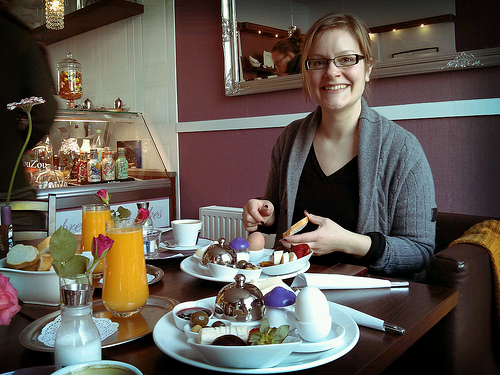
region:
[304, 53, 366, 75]
smiling woman wearing glasses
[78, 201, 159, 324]
two tall glasses of orange juice on table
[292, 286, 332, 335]
white boiled egg in shell in container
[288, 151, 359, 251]
woman wearing black v neck top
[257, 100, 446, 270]
woman wearing grey sweater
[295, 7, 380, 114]
A woman has a smile on her face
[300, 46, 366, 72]
A pair of black glasses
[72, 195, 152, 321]
Two glasses of orange juice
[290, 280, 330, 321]
A white hard boiled egg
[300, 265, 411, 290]
Utensils in a white napkin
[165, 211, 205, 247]
A white coffee cup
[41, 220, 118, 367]
Pink flower in a vase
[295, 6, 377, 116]
Woman has blonde hair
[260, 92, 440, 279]
Gray sweater and a black shirt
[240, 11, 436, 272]
A lady sitting at the table and smiling at the camera.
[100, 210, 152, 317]
A tall glass of juice.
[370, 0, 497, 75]
A mirror on the wall.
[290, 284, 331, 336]
An egg in a stand.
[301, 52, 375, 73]
Glasses on the ladies face.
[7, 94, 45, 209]
A flower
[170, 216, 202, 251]
A cup on a saucer.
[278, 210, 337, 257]
The ladies hand holding a slice of bread.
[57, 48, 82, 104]
A glass container with candy in it.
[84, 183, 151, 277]
Three roses on the table.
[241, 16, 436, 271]
Lady is eating breakfast.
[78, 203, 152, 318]
Glasses of orange juice.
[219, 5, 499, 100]
Mirror on wall behind woman.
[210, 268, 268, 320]
Silver domed cover over food.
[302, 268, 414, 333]
Silverware wrapped in white napkins.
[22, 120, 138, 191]
Food on top of case.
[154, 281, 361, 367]
Boiled eggs on white plate.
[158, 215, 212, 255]
white coffee cup on saucer.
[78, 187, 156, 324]
orange juice on silver platters with red roses near.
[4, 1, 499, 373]
Interior scene, suggestive of natural light.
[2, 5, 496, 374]
Restaurant interior, with person, suggestive of Easter breakfast.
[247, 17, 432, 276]
Casual, bespectacled, blonde woman, wearing sweater and black top.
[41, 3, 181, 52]
White, paneled wall, shelf and overhanging, decorative, light fixture.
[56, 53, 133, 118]
Decorative shakers and jar of candy, topping display case.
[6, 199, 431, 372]
Extra chair and table set with plates and glasses, full of food.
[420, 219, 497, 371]
Dark, wood table and bench,showing gold garment over armrest.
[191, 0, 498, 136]
Mauve wall, with white stripe, showing mirror with reflection.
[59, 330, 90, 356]
milk in a bottle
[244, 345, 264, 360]
a white bowl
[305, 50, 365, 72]
glasses on a woman's face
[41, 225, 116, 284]
flower in a milk jar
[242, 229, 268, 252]
brown egg on a platter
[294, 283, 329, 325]
white egg on a platter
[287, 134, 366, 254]
woman's black shirt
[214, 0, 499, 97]
mirror on the wall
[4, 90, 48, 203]
tall purple colored flower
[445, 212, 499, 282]
yellow material on the armchair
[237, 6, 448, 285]
woman seated at a table